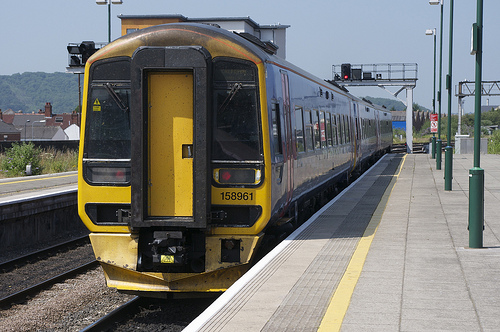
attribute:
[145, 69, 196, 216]
door — yellow, here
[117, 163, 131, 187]
light — red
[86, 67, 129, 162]
window — here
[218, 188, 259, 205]
number — here, black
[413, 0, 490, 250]
poles — green, here, lit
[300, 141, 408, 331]
line — yellow, here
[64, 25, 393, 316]
train — yellow, pulling, moving, here, approaching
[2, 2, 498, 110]
sky — blue, cloudless, here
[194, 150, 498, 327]
platform — gray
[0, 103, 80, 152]
buildings — several, here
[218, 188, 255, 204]
numbers — here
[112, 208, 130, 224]
metal — here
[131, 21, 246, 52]
roof — here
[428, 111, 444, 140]
sign — here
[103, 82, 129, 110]
wiper — here